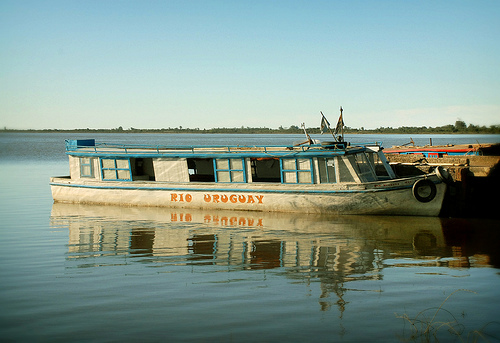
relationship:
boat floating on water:
[46, 107, 456, 222] [2, 133, 500, 343]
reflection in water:
[49, 197, 500, 328] [2, 133, 500, 343]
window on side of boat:
[184, 153, 219, 185] [46, 107, 456, 222]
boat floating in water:
[46, 107, 456, 222] [2, 133, 500, 343]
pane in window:
[211, 158, 250, 186] [184, 153, 219, 185]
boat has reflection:
[46, 107, 456, 222] [49, 197, 500, 328]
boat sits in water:
[46, 107, 456, 222] [2, 133, 500, 343]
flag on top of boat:
[332, 105, 348, 137] [46, 107, 456, 222]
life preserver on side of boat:
[410, 176, 440, 205] [46, 107, 456, 222]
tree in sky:
[454, 116, 469, 133] [2, 3, 498, 130]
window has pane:
[184, 153, 219, 185] [211, 158, 250, 186]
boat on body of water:
[46, 107, 456, 222] [2, 133, 500, 343]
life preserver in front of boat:
[410, 176, 440, 205] [46, 107, 456, 222]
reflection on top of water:
[49, 197, 500, 328] [2, 133, 500, 343]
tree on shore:
[454, 116, 469, 133] [2, 125, 500, 140]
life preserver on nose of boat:
[410, 176, 440, 205] [46, 107, 456, 222]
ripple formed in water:
[59, 244, 239, 265] [2, 133, 500, 343]